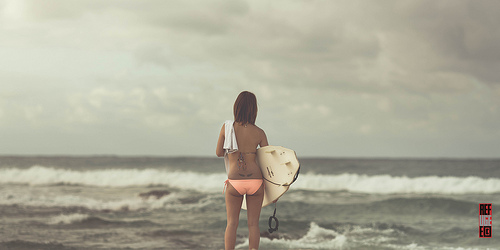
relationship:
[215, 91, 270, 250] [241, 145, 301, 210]
girl holding board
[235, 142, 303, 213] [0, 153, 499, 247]
board facing water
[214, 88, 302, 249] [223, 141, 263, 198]
girl wearing bikini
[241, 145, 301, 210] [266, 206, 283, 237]
board with leash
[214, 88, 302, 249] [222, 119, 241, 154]
girl with shirt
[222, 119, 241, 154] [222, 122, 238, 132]
shirt over shoulder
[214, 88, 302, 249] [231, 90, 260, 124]
girl with hair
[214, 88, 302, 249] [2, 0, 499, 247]
girl facing away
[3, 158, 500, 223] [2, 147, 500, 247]
wave in ocean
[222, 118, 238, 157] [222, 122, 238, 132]
towel over shoulder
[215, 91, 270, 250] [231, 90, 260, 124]
girl has hair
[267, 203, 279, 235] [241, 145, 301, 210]
tether hanging from board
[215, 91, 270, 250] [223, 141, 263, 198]
girl in bikini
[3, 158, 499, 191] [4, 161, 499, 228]
caps on waves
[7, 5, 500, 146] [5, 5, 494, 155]
clouds in sky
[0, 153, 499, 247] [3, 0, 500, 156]
water meeting horizon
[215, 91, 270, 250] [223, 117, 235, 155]
girl with something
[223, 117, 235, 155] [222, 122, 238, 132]
something on shoulder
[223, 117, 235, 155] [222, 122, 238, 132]
something draped on shoulder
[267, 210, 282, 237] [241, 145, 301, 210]
strap hanging down from board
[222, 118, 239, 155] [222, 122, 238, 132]
fabric over shoulder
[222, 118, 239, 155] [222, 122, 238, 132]
fabric hanging over shoulder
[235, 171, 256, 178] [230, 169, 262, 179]
tattoo on lower back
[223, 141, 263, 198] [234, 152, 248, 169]
bikini has strings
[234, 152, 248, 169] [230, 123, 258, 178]
strings down back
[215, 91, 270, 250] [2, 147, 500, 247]
girl looking at ocean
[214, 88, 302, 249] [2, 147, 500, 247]
girl before ocean